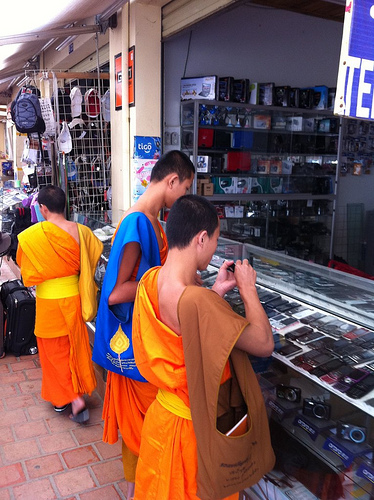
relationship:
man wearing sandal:
[10, 187, 101, 435] [71, 408, 89, 422]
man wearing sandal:
[10, 187, 101, 435] [46, 400, 69, 414]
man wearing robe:
[103, 149, 196, 500] [88, 213, 169, 461]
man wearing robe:
[130, 193, 274, 499] [128, 270, 240, 498]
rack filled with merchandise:
[35, 62, 141, 253] [15, 75, 110, 202]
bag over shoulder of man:
[173, 295, 283, 495] [130, 193, 274, 499]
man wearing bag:
[103, 149, 196, 500] [93, 213, 164, 382]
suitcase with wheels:
[2, 273, 41, 362] [5, 340, 36, 359]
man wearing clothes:
[14, 187, 101, 424] [19, 222, 103, 400]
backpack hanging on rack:
[10, 79, 43, 135] [19, 71, 109, 221]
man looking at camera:
[130, 193, 274, 499] [222, 258, 236, 273]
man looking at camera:
[103, 149, 196, 500] [222, 258, 236, 273]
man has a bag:
[130, 193, 274, 499] [172, 279, 274, 497]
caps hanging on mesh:
[59, 80, 117, 124] [22, 69, 114, 227]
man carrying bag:
[103, 149, 193, 408] [104, 228, 155, 387]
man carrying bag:
[14, 187, 101, 424] [78, 225, 102, 321]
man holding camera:
[130, 193, 274, 499] [222, 256, 245, 275]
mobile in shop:
[283, 324, 312, 338] [155, 16, 372, 498]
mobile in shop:
[295, 330, 328, 346] [155, 16, 372, 498]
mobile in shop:
[270, 316, 298, 329] [155, 16, 372, 498]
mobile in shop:
[301, 347, 340, 367] [155, 16, 372, 498]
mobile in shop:
[272, 338, 292, 352] [155, 16, 372, 498]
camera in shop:
[302, 391, 331, 420] [155, 16, 372, 498]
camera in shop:
[275, 378, 301, 404] [155, 16, 372, 498]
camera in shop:
[333, 415, 366, 446] [155, 16, 372, 498]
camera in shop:
[333, 415, 366, 446] [2, 22, 121, 346]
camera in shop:
[275, 378, 301, 404] [2, 22, 121, 346]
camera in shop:
[302, 391, 331, 420] [2, 22, 121, 346]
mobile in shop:
[272, 338, 292, 352] [2, 22, 121, 346]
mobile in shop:
[301, 347, 340, 367] [2, 22, 121, 346]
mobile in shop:
[270, 316, 298, 329] [2, 22, 121, 346]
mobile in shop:
[295, 330, 328, 346] [2, 22, 121, 346]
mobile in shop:
[283, 324, 312, 338] [2, 22, 121, 346]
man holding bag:
[130, 193, 274, 499] [172, 279, 274, 497]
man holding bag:
[14, 187, 101, 424] [93, 213, 164, 382]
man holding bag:
[130, 193, 274, 499] [93, 213, 164, 382]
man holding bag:
[103, 149, 196, 500] [93, 213, 164, 382]